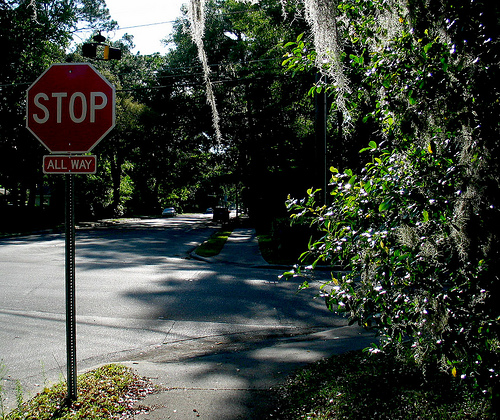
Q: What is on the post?
A: Stop sign.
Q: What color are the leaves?
A: Green.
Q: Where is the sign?
A: On the corner.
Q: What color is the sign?
A: Red.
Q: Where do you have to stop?
A: In front of the sign.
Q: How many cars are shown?
A: 1.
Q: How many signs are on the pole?
A: 2.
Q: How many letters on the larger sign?
A: 4.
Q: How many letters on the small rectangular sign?
A: 6.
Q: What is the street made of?
A: Asphalt.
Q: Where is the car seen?
A: In street.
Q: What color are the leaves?
A: Green.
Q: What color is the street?
A: Gray.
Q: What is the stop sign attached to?
A: Metal pole.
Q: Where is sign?
A: On sidewalk.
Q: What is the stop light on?
A: Power line.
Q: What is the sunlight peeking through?
A: Shaded area.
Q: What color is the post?
A: Green.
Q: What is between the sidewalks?
A: Street.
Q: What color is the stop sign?
A: Red.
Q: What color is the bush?
A: Green.